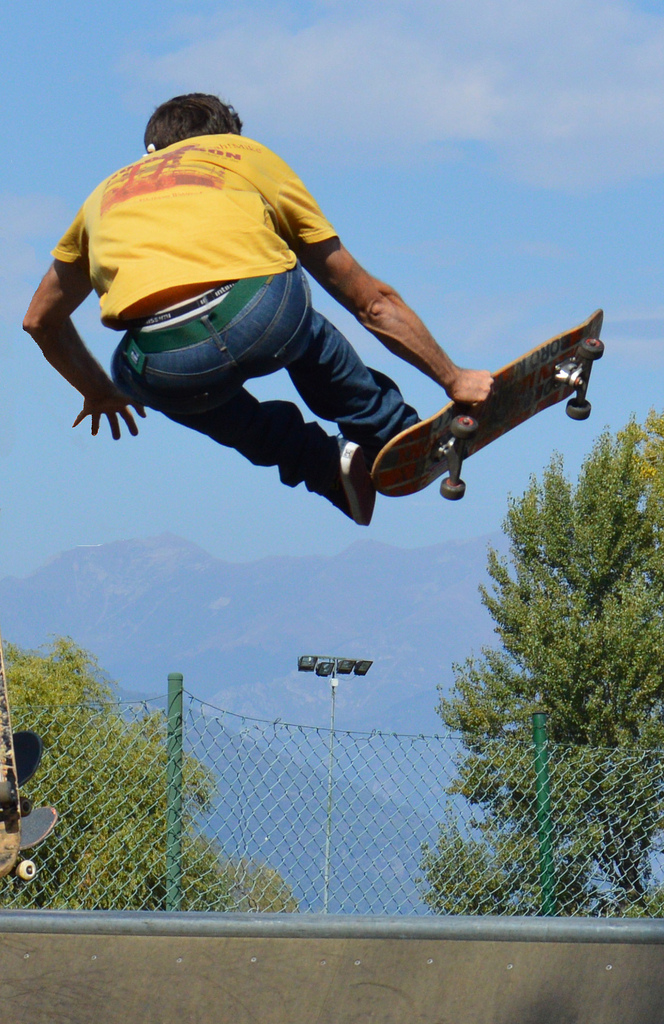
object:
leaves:
[494, 562, 562, 606]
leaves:
[635, 698, 658, 737]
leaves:
[553, 685, 591, 748]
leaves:
[617, 562, 628, 642]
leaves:
[117, 841, 146, 887]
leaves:
[502, 592, 538, 650]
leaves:
[590, 717, 605, 763]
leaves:
[570, 841, 609, 877]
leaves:
[494, 807, 538, 873]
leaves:
[459, 803, 484, 877]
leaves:
[590, 673, 648, 752]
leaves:
[552, 599, 619, 700]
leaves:
[109, 814, 127, 849]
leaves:
[178, 841, 265, 913]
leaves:
[90, 712, 167, 808]